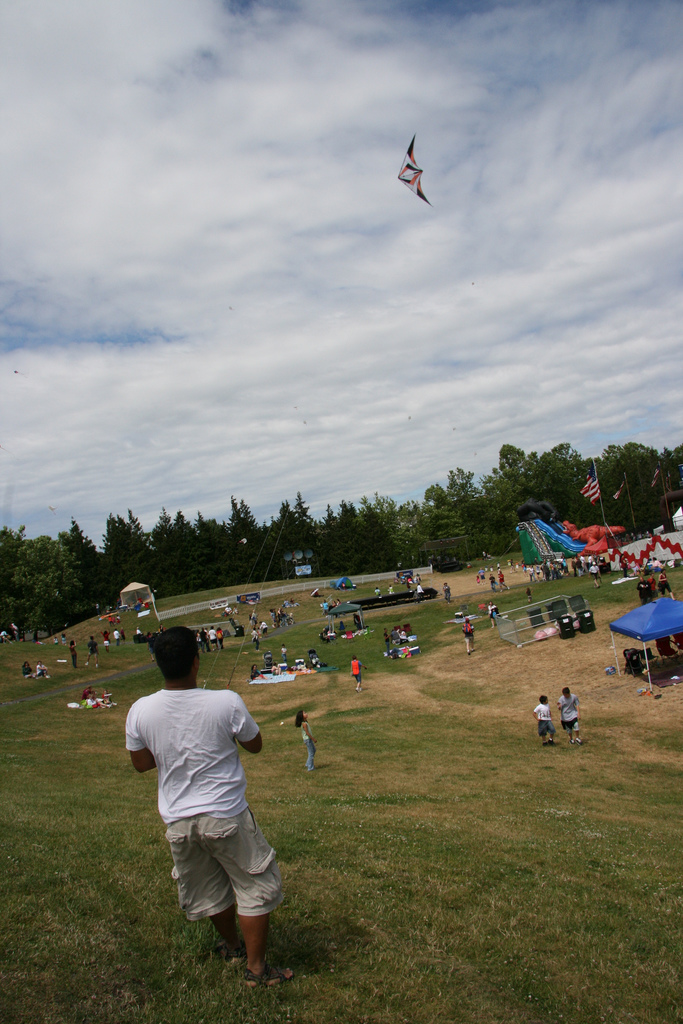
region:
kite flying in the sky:
[396, 131, 433, 207]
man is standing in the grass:
[122, 627, 300, 991]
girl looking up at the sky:
[291, 709, 324, 779]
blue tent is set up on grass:
[606, 595, 682, 697]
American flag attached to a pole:
[581, 455, 629, 572]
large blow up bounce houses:
[512, 513, 611, 568]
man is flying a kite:
[118, 624, 297, 991]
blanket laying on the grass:
[247, 668, 296, 685]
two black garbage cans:
[554, 609, 599, 641]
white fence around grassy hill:
[150, 560, 435, 624]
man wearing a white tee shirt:
[119, 677, 255, 813]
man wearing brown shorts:
[153, 802, 282, 928]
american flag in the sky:
[566, 452, 607, 508]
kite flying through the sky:
[389, 127, 438, 207]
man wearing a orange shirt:
[346, 655, 365, 678]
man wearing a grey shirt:
[553, 690, 578, 719]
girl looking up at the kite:
[288, 705, 323, 768]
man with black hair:
[145, 615, 205, 685]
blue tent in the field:
[612, 588, 682, 650]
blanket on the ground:
[249, 670, 292, 685]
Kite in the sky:
[389, 129, 437, 212]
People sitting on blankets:
[238, 643, 336, 693]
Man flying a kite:
[114, 620, 297, 959]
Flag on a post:
[575, 457, 608, 504]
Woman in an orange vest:
[343, 648, 368, 697]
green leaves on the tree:
[474, 498, 499, 521]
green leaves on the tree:
[403, 528, 420, 537]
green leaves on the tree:
[265, 534, 288, 549]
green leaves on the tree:
[357, 498, 407, 558]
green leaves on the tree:
[173, 512, 219, 552]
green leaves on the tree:
[105, 467, 186, 547]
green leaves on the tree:
[134, 496, 217, 585]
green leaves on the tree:
[46, 518, 86, 562]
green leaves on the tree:
[169, 483, 247, 605]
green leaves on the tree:
[234, 473, 265, 508]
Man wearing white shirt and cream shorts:
[124, 624, 292, 985]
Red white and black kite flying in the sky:
[397, 131, 434, 209]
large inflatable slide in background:
[513, 495, 622, 562]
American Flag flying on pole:
[577, 453, 604, 568]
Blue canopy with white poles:
[606, 596, 677, 683]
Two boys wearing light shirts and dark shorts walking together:
[527, 683, 586, 745]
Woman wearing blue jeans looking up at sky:
[294, 707, 321, 771]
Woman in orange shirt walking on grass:
[348, 648, 361, 684]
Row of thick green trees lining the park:
[0, 438, 677, 633]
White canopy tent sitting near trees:
[118, 580, 155, 610]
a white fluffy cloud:
[417, 281, 471, 327]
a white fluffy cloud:
[204, 419, 254, 459]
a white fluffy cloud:
[353, 279, 493, 409]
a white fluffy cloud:
[476, 234, 600, 335]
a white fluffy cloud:
[85, 195, 176, 290]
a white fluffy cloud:
[193, 175, 276, 309]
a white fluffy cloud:
[265, 173, 477, 457]